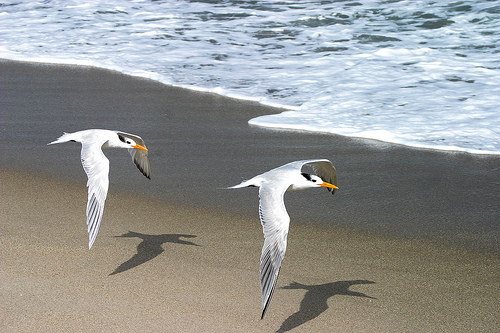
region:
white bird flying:
[40, 107, 163, 262]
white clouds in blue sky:
[415, 17, 450, 72]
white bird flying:
[200, 135, 340, 302]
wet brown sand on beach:
[20, 10, 100, 63]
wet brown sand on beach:
[190, 17, 243, 77]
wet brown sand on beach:
[356, 177, 403, 213]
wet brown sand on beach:
[410, 192, 480, 258]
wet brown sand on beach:
[151, 185, 186, 221]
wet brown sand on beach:
[33, 271, 86, 307]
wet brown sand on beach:
[112, 26, 184, 86]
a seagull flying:
[50, 111, 159, 261]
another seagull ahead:
[216, 140, 339, 316]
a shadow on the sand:
[281, 258, 383, 330]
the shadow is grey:
[107, 217, 197, 280]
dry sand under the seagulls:
[4, 159, 481, 327]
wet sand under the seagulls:
[2, 59, 497, 246]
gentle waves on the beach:
[0, 10, 498, 157]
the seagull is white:
[47, 118, 152, 248]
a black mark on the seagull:
[114, 130, 124, 143]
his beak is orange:
[130, 142, 149, 156]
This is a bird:
[51, 99, 171, 257]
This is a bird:
[217, 120, 368, 327]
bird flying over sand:
[38, 101, 160, 266]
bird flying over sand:
[227, 142, 351, 306]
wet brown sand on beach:
[40, 18, 81, 63]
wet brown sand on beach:
[87, 41, 147, 111]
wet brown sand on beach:
[145, 208, 196, 242]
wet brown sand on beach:
[30, 232, 75, 303]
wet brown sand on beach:
[302, 246, 369, 328]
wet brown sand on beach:
[360, 208, 455, 290]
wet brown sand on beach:
[355, 108, 432, 176]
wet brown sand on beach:
[181, 76, 249, 136]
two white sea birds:
[41, 112, 351, 317]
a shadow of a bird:
[263, 253, 379, 324]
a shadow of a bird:
[106, 220, 205, 273]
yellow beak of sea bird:
[132, 138, 150, 156]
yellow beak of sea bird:
[318, 178, 343, 191]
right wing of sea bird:
[246, 185, 296, 320]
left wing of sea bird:
[283, 144, 344, 175]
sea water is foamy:
[0, 0, 491, 130]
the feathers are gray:
[251, 238, 296, 315]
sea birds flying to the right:
[41, 105, 375, 320]